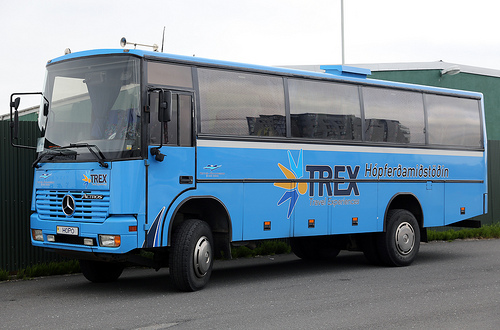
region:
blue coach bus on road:
[6, 37, 489, 279]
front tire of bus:
[172, 217, 216, 291]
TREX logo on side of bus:
[268, 150, 361, 217]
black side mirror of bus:
[146, 85, 172, 160]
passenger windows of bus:
[194, 64, 484, 154]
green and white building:
[1, 59, 498, 221]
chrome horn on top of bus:
[118, 36, 158, 51]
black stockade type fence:
[0, 117, 85, 267]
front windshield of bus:
[33, 56, 142, 152]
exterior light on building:
[437, 64, 460, 79]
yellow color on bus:
[283, 172, 297, 182]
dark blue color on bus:
[286, 194, 298, 200]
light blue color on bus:
[294, 159, 304, 170]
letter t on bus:
[303, 160, 320, 200]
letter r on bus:
[318, 164, 334, 200]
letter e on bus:
[331, 161, 347, 197]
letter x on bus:
[346, 160, 361, 194]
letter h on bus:
[364, 158, 373, 180]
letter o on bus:
[371, 165, 378, 179]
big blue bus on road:
[31, 41, 498, 303]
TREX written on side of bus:
[297, 159, 365, 203]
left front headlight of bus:
[92, 227, 123, 253]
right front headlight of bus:
[26, 223, 48, 245]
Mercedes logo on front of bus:
[51, 189, 81, 220]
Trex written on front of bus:
[81, 167, 111, 190]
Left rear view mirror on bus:
[144, 79, 184, 155]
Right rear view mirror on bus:
[2, 82, 54, 161]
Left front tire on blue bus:
[163, 203, 235, 300]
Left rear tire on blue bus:
[375, 188, 430, 272]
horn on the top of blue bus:
[112, 32, 167, 60]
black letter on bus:
[306, 162, 327, 198]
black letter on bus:
[319, 160, 339, 204]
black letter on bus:
[334, 155, 346, 204]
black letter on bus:
[344, 147, 366, 207]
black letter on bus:
[362, 154, 372, 185]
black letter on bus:
[372, 158, 379, 180]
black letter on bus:
[382, 156, 397, 181]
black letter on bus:
[394, 158, 406, 183]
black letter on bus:
[407, 160, 413, 187]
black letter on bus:
[411, 160, 427, 187]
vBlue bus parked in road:
[23, 21, 356, 310]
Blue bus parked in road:
[23, 21, 478, 250]